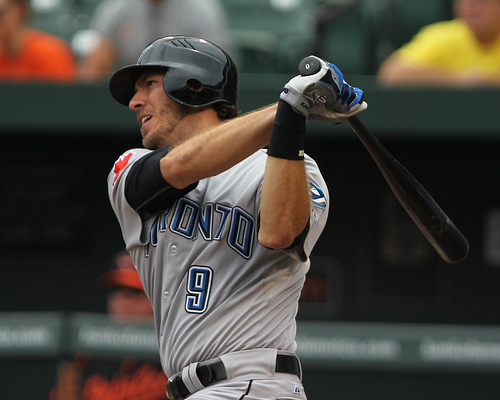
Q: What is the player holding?
A: A baseball bat.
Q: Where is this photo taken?
A: On a baseball field.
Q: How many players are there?
A: One.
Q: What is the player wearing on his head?
A: A helmet.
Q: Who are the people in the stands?
A: Spectators.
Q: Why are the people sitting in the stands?
A: They are watching the baseball game.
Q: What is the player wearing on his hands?
A: Gloves.